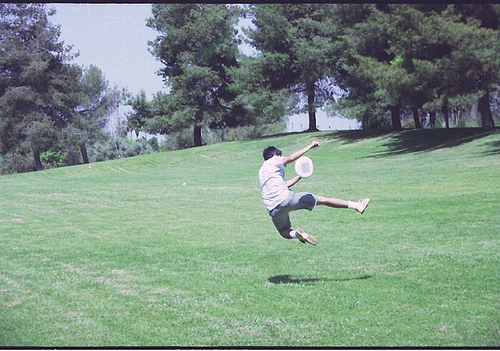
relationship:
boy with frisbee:
[263, 133, 350, 244] [294, 157, 316, 179]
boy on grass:
[263, 133, 350, 244] [117, 191, 196, 260]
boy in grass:
[263, 133, 350, 244] [117, 191, 196, 260]